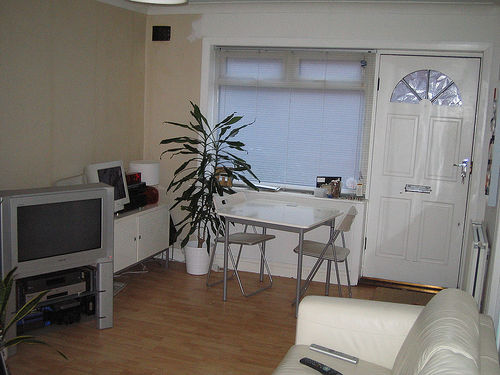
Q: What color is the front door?
A: White.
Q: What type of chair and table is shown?
A: Folding.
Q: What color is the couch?
A: White.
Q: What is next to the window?
A: A green plant.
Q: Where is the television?
A: On the television stand.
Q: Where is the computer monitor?
A: On the white shelf.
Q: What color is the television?
A: Silver.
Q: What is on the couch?
A: Remote controls.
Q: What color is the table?
A: White.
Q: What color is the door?
A: White.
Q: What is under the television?
A: A vcr.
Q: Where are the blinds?
A: On the window.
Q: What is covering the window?
A: Blinds.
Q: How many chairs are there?
A: 2.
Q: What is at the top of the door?
A: Window.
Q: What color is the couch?
A: White.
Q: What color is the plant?
A: Green.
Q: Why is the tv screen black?
A: Turned off.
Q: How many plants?
A: 1.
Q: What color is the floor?
A: Brown.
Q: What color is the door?
A: White.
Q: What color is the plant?
A: Green.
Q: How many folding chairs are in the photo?
A: 2.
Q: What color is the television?
A: Gray.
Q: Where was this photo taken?
A: In the living room.